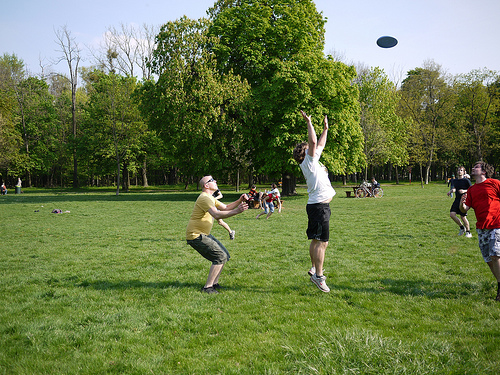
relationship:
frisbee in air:
[375, 37, 398, 48] [0, 2, 498, 373]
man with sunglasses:
[183, 174, 250, 295] [249, 189, 258, 195]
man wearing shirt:
[460, 162, 499, 280] [464, 177, 499, 230]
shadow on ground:
[78, 279, 206, 291] [3, 179, 499, 374]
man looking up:
[460, 162, 499, 280] [0, 2, 498, 195]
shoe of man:
[310, 275, 330, 292] [299, 111, 337, 292]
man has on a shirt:
[460, 162, 499, 280] [464, 177, 499, 230]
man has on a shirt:
[186, 174, 247, 292] [185, 193, 227, 242]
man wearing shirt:
[186, 174, 247, 292] [185, 193, 227, 242]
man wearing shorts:
[299, 111, 337, 292] [307, 201, 332, 242]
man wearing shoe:
[186, 174, 247, 292] [197, 285, 218, 293]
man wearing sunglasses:
[183, 174, 250, 295] [249, 189, 258, 195]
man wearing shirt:
[299, 111, 337, 292] [299, 151, 335, 205]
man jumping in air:
[299, 111, 337, 292] [0, 2, 498, 373]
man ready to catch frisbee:
[186, 174, 247, 292] [375, 37, 398, 48]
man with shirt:
[299, 111, 337, 292] [299, 151, 335, 205]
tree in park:
[198, 2, 328, 192] [0, 2, 499, 374]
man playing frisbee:
[299, 111, 337, 292] [375, 37, 398, 48]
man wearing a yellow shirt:
[186, 174, 247, 292] [185, 193, 227, 242]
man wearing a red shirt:
[460, 162, 499, 280] [464, 177, 499, 230]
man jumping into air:
[299, 111, 337, 292] [0, 2, 498, 373]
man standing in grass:
[186, 174, 247, 292] [3, 179, 499, 374]